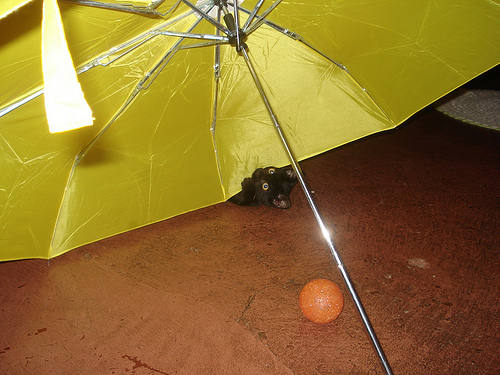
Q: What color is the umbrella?
A: Yellow.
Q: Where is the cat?
A: Ground.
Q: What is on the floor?
A: Orange.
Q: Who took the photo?
A: Owner.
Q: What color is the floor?
A: Brown.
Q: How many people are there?
A: Zero.